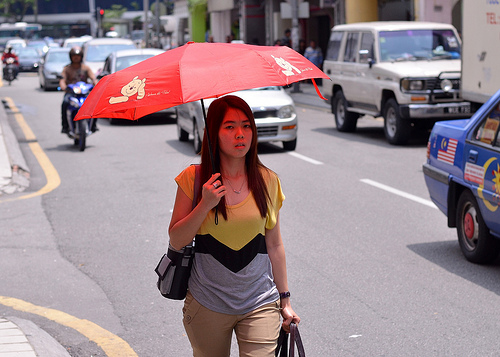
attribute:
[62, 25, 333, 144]
umbrella — red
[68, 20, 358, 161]
umbrella — red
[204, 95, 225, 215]
hair — straight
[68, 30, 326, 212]
umbrella — red, open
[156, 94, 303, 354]
woman — wearing pants, in the photo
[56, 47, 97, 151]
motorcycle — on the road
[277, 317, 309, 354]
holding straps — to purse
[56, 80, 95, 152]
blue motorcycle — in motion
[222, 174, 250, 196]
necklace — on the woman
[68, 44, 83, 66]
helmet — on the man riding motorcycle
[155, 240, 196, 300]
black canteen — small, with phone pocket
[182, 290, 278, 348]
khaki pants — on the woman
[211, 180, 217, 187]
ring — on womans finger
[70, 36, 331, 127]
red umbrella — big animated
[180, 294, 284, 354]
brown pants — in the photo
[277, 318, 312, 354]
handbag — in the photo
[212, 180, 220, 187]
ring — on the finger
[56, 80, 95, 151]
bike — in the photo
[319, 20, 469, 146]
truck — in the photo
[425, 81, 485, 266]
cab — in the photo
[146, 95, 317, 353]
woman — carrying an umbrella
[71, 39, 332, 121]
umbrella — in girl's hand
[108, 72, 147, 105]
character — on the umbrella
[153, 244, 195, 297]
bag — on the woman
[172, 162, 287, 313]
blouse — on the woman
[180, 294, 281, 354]
pants — on the woman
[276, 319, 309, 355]
straps — in the woman's hands